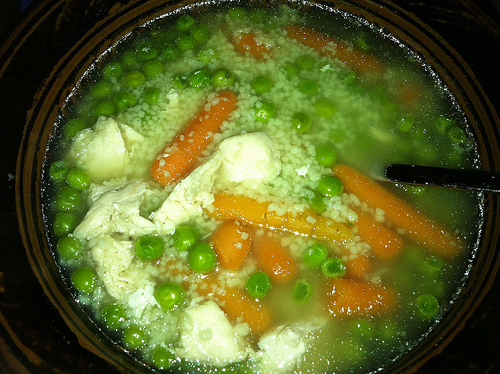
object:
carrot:
[331, 165, 462, 262]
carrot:
[214, 193, 356, 253]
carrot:
[316, 276, 399, 317]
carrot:
[203, 221, 263, 270]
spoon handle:
[384, 162, 498, 191]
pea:
[188, 243, 218, 273]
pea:
[152, 282, 186, 310]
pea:
[318, 174, 345, 196]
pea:
[316, 142, 336, 165]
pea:
[66, 166, 92, 191]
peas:
[67, 266, 103, 294]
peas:
[208, 66, 237, 89]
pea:
[244, 270, 270, 298]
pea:
[146, 346, 176, 370]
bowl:
[16, 1, 499, 374]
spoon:
[382, 163, 499, 193]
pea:
[173, 221, 199, 250]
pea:
[133, 235, 163, 262]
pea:
[54, 214, 79, 238]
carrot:
[151, 89, 239, 186]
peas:
[304, 243, 328, 264]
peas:
[56, 236, 86, 265]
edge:
[13, 97, 69, 297]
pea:
[118, 70, 145, 90]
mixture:
[52, 9, 476, 371]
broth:
[47, 8, 479, 371]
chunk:
[65, 114, 129, 178]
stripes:
[28, 150, 40, 235]